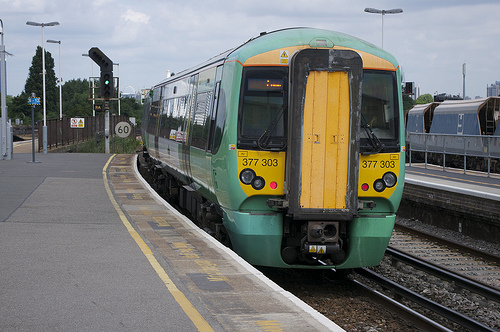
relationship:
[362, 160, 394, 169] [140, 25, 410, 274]
numbers on train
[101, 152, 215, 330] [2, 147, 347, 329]
line on platform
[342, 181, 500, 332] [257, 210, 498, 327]
track on ground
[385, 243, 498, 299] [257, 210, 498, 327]
track on ground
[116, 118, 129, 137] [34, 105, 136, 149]
number 60 on fence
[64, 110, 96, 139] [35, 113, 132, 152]
sign on fence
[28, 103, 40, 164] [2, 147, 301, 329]
pole on sidewalk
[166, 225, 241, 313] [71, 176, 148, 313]
words on platform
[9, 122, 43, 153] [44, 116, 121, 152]
street along fence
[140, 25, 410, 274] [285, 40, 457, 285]
train at train station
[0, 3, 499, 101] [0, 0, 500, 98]
clouds in blue sky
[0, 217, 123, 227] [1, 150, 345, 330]
crack in concrete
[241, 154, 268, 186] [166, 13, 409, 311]
lights on train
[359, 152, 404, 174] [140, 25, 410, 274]
numbers on train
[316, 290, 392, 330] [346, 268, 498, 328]
pebbles near tracks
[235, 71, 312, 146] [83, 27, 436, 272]
window on train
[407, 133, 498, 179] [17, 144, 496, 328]
railing on platform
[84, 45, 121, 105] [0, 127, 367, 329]
traffic light near platform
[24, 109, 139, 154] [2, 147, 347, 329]
fence near platform